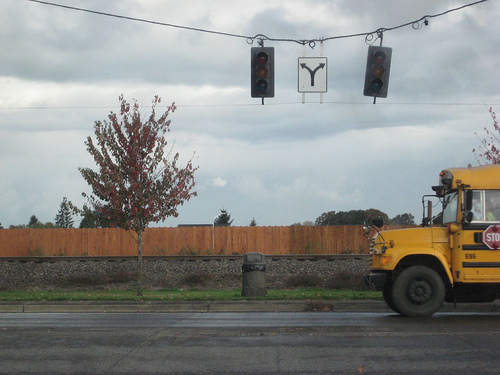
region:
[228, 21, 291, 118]
traffic light hanging above the road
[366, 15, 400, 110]
traffic light hanging above the road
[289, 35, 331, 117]
traffic sign hanging above the road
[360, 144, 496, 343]
front end of school bus on road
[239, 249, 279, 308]
gray trash can along the road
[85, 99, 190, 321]
red maple street on the road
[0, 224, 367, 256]
a light wooden fence bordering a yard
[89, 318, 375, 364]
semi wet road with a bus on it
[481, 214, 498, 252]
stop sign on the side of bus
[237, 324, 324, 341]
dirt laying in middle of street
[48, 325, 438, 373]
The street is made is asphalt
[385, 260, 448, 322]
The front tire of the bus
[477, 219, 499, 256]
The stop sign is red and white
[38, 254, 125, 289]
The cement wall is the color gray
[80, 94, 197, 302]
The tree has pink leaves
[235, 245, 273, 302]
The trash can on the side of the road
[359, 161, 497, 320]
The school bus is the color yellow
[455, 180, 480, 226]
The rear view mirror on the bus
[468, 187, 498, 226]
The window on the side of the bus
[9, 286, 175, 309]
The grass is short and green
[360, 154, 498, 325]
front of school bus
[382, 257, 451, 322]
front wheel on school bus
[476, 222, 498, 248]
school bus stop sign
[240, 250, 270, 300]
trash can on grass area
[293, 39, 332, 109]
black and white street sign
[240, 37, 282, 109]
traffic light to left of sign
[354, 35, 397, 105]
traffic light to right of sign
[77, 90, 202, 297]
tree near trash can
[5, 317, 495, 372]
street where bus is located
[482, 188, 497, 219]
window on the bus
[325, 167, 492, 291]
yellow school bus on right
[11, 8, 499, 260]
white clouds in sky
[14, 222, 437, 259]
wood fence along road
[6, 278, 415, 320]
green grass growing on ground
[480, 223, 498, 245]
small stop sign on bus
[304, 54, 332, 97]
white square arrows sign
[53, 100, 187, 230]
red leaves on small tree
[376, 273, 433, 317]
round black rubber bus tire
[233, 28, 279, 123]
stop light hanging over road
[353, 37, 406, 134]
stop light hanging over road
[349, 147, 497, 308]
school bus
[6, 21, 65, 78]
white clouds in blue sky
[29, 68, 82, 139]
white clouds in blue sky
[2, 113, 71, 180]
white clouds in blue sky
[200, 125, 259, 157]
white clouds in blue sky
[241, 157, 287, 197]
white clouds in blue sky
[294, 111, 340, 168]
white clouds in blue sky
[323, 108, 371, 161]
white clouds in blue sky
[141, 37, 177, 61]
white clouds in blue sky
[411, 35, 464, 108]
white clouds in blue sky